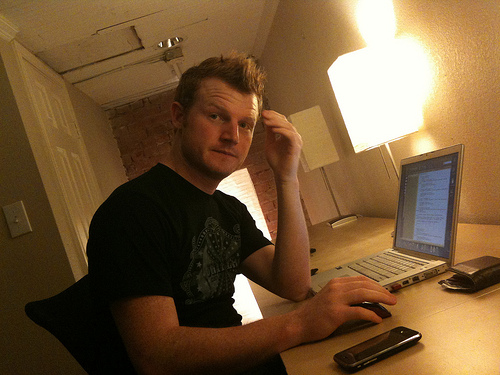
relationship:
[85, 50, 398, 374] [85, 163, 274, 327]
man wearing shirt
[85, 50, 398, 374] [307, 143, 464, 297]
man at laptop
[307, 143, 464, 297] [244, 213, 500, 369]
laptop on desk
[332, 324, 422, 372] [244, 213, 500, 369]
phone on desk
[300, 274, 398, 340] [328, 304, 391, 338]
right hand on mouse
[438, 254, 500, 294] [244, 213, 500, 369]
wallet on desk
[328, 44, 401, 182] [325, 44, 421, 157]
lamp has shade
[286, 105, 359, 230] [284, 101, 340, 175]
lamp has shade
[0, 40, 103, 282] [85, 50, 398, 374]
door behind man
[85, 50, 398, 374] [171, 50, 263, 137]
man has hair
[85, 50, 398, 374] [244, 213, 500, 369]
man sitting at desk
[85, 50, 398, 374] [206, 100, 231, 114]
man has brow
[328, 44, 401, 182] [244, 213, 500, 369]
lamp on desk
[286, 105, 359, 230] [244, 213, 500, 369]
lamp on desk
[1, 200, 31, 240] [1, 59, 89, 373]
light switch on wall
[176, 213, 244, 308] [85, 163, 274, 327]
design on shirt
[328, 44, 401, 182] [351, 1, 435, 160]
lamp has reflection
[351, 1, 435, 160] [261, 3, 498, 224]
reflection on wall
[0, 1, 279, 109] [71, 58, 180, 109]
ceiling has attic access